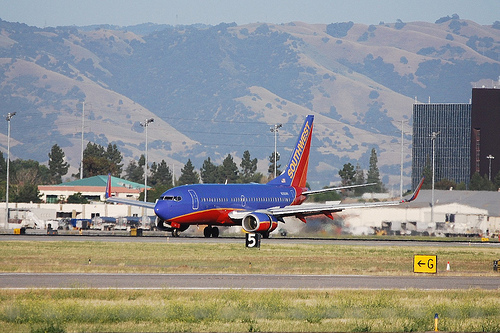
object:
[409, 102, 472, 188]
buildings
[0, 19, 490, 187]
mountain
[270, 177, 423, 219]
wings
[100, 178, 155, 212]
large wing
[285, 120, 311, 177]
name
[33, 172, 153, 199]
building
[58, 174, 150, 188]
roof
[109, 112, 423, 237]
airplane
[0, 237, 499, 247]
ground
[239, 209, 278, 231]
engine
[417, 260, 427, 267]
arrow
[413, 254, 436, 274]
sign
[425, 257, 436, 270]
g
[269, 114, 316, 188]
plane's tail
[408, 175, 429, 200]
tip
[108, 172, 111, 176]
tip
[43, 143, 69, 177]
trees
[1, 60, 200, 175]
hills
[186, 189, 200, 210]
door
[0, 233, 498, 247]
runway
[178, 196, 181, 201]
window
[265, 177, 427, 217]
large wing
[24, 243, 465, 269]
ground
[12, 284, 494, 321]
ground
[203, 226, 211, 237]
wheels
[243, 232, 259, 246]
5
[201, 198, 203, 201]
window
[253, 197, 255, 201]
window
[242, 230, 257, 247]
number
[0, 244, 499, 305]
ground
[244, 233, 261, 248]
sign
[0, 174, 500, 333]
airport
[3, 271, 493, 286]
runway